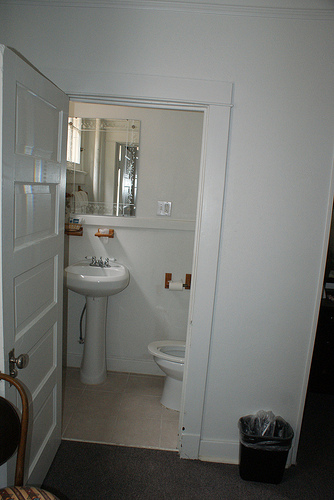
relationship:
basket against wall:
[237, 413, 294, 486] [179, 16, 325, 466]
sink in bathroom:
[63, 256, 131, 293] [60, 101, 194, 452]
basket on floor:
[237, 413, 294, 486] [39, 437, 332, 498]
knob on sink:
[105, 256, 117, 262] [86, 252, 117, 271]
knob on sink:
[83, 254, 98, 265] [64, 254, 128, 386]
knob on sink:
[104, 254, 114, 265] [64, 254, 128, 386]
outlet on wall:
[153, 197, 178, 214] [74, 106, 192, 373]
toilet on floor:
[146, 338, 183, 411] [61, 366, 180, 450]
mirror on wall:
[67, 115, 136, 219] [67, 100, 203, 365]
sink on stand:
[63, 256, 131, 297] [77, 295, 109, 386]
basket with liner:
[236, 408, 294, 478] [234, 410, 294, 454]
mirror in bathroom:
[67, 115, 136, 219] [70, 99, 186, 381]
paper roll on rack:
[159, 270, 204, 301] [159, 270, 192, 291]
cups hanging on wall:
[99, 228, 109, 244] [64, 225, 196, 376]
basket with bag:
[237, 413, 294, 486] [236, 409, 294, 451]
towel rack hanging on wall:
[65, 185, 89, 206] [68, 120, 88, 212]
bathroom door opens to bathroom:
[0, 44, 77, 484] [59, 93, 205, 459]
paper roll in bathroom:
[169, 281, 184, 291] [32, 180, 223, 473]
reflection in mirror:
[64, 116, 139, 201] [62, 112, 144, 218]